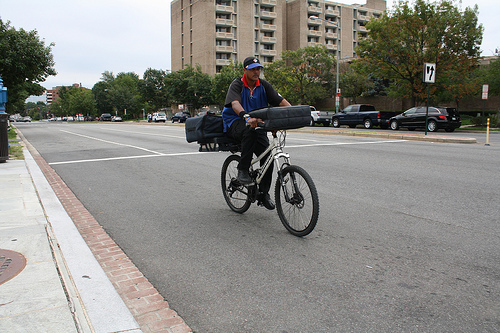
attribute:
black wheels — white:
[217, 159, 334, 238]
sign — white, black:
[416, 62, 441, 87]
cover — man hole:
[6, 242, 27, 302]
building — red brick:
[193, 13, 215, 48]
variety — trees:
[84, 72, 179, 109]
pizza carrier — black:
[239, 94, 316, 135]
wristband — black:
[236, 112, 250, 119]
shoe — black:
[227, 168, 255, 186]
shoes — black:
[237, 169, 287, 218]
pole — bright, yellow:
[481, 126, 484, 153]